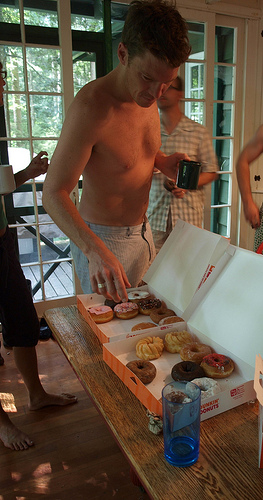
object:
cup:
[160, 377, 200, 467]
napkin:
[146, 409, 164, 436]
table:
[43, 294, 263, 497]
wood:
[42, 301, 261, 498]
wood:
[1, 314, 155, 498]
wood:
[229, 1, 262, 249]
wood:
[58, 0, 73, 135]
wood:
[111, 0, 262, 28]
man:
[236, 122, 263, 253]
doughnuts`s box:
[102, 243, 262, 430]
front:
[102, 344, 173, 431]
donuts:
[201, 354, 236, 377]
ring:
[97, 282, 105, 288]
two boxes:
[75, 219, 263, 431]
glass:
[176, 160, 203, 190]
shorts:
[249, 202, 263, 256]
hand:
[88, 245, 131, 304]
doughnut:
[165, 329, 198, 354]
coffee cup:
[0, 163, 16, 195]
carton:
[103, 243, 263, 430]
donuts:
[125, 359, 156, 383]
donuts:
[170, 360, 205, 382]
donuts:
[134, 335, 163, 360]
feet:
[28, 389, 78, 412]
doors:
[1, 0, 252, 318]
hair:
[119, 1, 192, 69]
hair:
[175, 76, 182, 90]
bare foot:
[25, 390, 79, 412]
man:
[0, 53, 78, 453]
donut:
[86, 304, 113, 323]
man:
[151, 74, 218, 238]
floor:
[0, 323, 151, 497]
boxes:
[76, 219, 261, 430]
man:
[41, 0, 192, 306]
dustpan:
[124, 323, 196, 367]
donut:
[113, 301, 139, 320]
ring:
[182, 190, 184, 194]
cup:
[175, 155, 202, 193]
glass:
[160, 379, 199, 467]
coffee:
[177, 158, 202, 190]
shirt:
[146, 113, 218, 235]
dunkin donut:
[171, 359, 208, 382]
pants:
[69, 216, 156, 295]